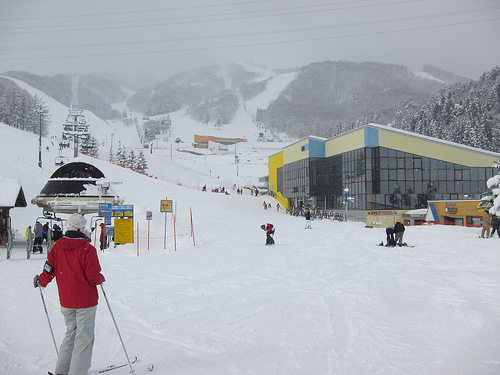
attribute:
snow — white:
[287, 242, 349, 301]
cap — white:
[61, 212, 93, 232]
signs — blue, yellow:
[91, 199, 149, 254]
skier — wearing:
[23, 210, 104, 373]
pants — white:
[54, 300, 102, 374]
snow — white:
[12, 70, 290, 185]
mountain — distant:
[217, 71, 303, 129]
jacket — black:
[302, 210, 312, 220]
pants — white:
[304, 218, 310, 226]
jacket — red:
[56, 243, 90, 293]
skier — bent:
[394, 219, 406, 244]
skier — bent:
[386, 225, 394, 240]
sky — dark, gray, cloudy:
[1, 0, 499, 90]